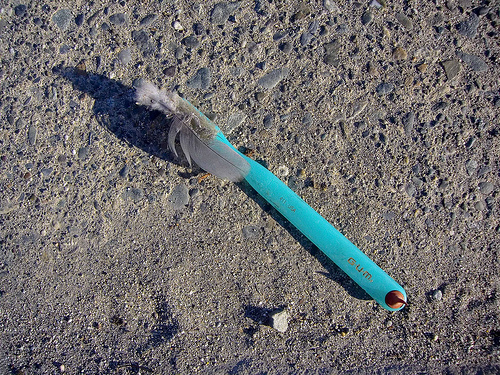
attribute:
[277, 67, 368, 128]
surface — gray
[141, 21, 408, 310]
toothbrush — pointy, blue, laying, rubber, dirty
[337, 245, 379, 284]
lettering — gold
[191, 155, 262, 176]
feather — fluffy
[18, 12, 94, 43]
pebble — grey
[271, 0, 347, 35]
rocks — concrete